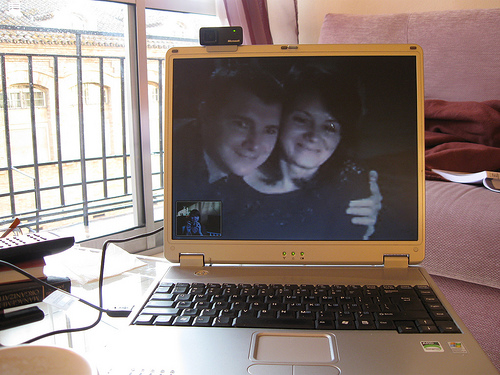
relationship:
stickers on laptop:
[419, 339, 444, 353] [114, 42, 484, 367]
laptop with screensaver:
[114, 42, 484, 367] [171, 56, 420, 239]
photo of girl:
[172, 199, 221, 237] [179, 206, 205, 238]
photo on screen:
[172, 199, 221, 237] [169, 56, 422, 239]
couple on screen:
[177, 68, 415, 238] [169, 56, 422, 239]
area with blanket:
[427, 94, 479, 282] [422, 99, 498, 183]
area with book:
[427, 94, 479, 282] [430, 164, 481, 184]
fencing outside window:
[6, 23, 186, 225] [5, 5, 223, 247]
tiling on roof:
[10, 10, 196, 30] [7, 3, 195, 43]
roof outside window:
[7, 3, 195, 43] [3, 9, 227, 232]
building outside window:
[6, 9, 210, 209] [4, 4, 209, 258]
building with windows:
[6, 9, 210, 209] [11, 77, 158, 173]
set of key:
[394, 314, 463, 334] [440, 322, 458, 335]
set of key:
[394, 314, 463, 334] [418, 323, 439, 333]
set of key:
[394, 314, 463, 334] [398, 321, 416, 332]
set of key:
[394, 314, 463, 334] [417, 315, 433, 323]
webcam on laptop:
[194, 26, 246, 46] [114, 42, 484, 367]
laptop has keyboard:
[114, 42, 484, 367] [138, 273, 467, 336]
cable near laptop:
[89, 236, 122, 326] [114, 42, 484, 367]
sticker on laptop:
[445, 337, 465, 354] [114, 42, 484, 367]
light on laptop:
[278, 251, 289, 259] [114, 42, 484, 367]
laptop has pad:
[114, 42, 484, 367] [255, 334, 332, 360]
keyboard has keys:
[141, 270, 455, 330] [399, 313, 449, 332]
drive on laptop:
[105, 287, 133, 329] [146, 5, 465, 372]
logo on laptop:
[276, 40, 299, 52] [144, 24, 484, 360]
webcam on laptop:
[189, 14, 249, 56] [146, 5, 465, 372]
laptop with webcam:
[114, 42, 484, 367] [198, 26, 246, 46]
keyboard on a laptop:
[127, 282, 461, 333] [114, 42, 484, 367]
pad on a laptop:
[256, 325, 336, 368] [169, 38, 480, 372]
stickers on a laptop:
[413, 331, 470, 361] [144, 24, 484, 360]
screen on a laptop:
[182, 66, 416, 252] [144, 24, 484, 360]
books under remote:
[4, 252, 50, 322] [0, 230, 75, 262]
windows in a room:
[13, 3, 151, 236] [17, 5, 484, 273]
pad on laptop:
[255, 334, 332, 360] [144, 24, 484, 360]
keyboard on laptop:
[127, 282, 461, 333] [144, 24, 484, 360]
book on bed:
[429, 168, 499, 192] [430, 185, 478, 280]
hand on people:
[345, 162, 391, 228] [207, 67, 373, 244]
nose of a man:
[243, 111, 266, 152] [195, 72, 282, 192]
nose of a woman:
[305, 126, 325, 140] [283, 92, 363, 180]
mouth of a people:
[294, 140, 330, 157] [207, 67, 373, 244]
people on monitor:
[205, 76, 385, 181] [138, 24, 438, 255]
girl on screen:
[179, 206, 205, 238] [169, 56, 422, 239]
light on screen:
[276, 246, 288, 259] [171, 57, 416, 242]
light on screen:
[286, 249, 300, 259] [171, 57, 416, 242]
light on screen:
[295, 249, 309, 259] [171, 57, 416, 242]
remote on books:
[2, 222, 74, 263] [4, 257, 72, 310]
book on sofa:
[429, 162, 498, 194] [423, 171, 498, 365]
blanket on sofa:
[422, 93, 498, 179] [318, 8, 498, 369]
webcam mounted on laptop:
[198, 26, 246, 46] [114, 42, 484, 367]